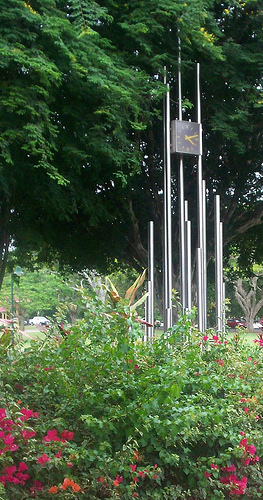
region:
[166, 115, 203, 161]
The clock on the poles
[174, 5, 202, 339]
The poles the clock is on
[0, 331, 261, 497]
Red flowers on the bushes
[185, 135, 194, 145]
Clock's hour hand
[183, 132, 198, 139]
Clock's minute hand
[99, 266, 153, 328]
Bird of paradise flower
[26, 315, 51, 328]
White truck in background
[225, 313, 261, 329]
Red car in the background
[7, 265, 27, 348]
Lamp post in park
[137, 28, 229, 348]
Tall metal poles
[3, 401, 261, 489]
Flowers are pink color.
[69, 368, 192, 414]
Leaves are green color.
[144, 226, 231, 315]
Poles are silver color.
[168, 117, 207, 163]
Clock is fixed in poles.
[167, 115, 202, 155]
Clock is blue and yellow.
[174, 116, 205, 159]
4.13 is the time shown in clock.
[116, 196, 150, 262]
Woods are brown color.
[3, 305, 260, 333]
Cars are parked behind the trees.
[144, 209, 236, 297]
Fourteen poles are standing.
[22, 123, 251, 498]
Day time picture.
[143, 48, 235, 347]
a clock on poles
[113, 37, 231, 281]
a clock in the air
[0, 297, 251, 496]
a bush in front of the poles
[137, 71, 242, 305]
a clock during the day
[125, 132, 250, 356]
many different size poles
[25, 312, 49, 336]
a vehicle in the distance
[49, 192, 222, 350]
a large tree behind the poles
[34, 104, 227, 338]
a large tree behind the clock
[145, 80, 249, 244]
a clock outside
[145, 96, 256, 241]
a clock on three poles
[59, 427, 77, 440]
a pink flower in the bush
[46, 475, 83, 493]
an orange flower in the bush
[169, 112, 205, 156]
a square black clock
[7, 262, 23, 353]
a green lamp post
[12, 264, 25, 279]
a green street light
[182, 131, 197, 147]
the yellow hands of a clock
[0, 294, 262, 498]
a large green bush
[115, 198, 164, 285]
the branch of a tree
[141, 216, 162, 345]
a large metal pipe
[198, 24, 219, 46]
yellow flowers in the tree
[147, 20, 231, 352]
A WIND CHIME ON A TREE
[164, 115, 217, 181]
A CLOCK ON WIND CHIMES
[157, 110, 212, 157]
IT'S 4:12 ON THE CLOCK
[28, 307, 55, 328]
A WHITE CAR IN THE DISTANCE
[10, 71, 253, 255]
A LARGE TREE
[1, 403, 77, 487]
PINK FLOWERS IN THE BUSH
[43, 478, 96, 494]
ORANGE FLOWERS IN THE BUSH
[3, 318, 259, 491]
A BUSH WITH FLOWERS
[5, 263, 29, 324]
A POLE WITH A FLAG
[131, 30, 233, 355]
A METAL WIND CHIME WITH A CLOCK